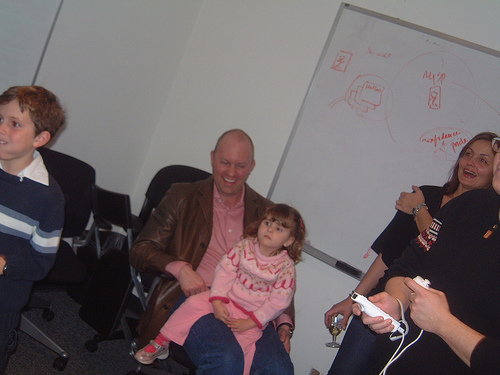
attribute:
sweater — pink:
[218, 235, 300, 330]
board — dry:
[259, 6, 499, 290]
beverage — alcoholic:
[321, 310, 346, 352]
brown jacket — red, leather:
[128, 152, 295, 358]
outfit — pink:
[160, 236, 297, 373]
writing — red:
[330, 50, 487, 162]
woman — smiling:
[370, 125, 490, 200]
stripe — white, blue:
[0, 205, 62, 260]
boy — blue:
[2, 81, 70, 358]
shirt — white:
[5, 157, 71, 308]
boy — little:
[0, 81, 75, 373]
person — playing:
[120, 82, 373, 362]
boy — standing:
[5, 73, 94, 349]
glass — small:
[323, 312, 344, 348]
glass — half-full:
[324, 314, 344, 348]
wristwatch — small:
[271, 325, 317, 337]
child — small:
[133, 200, 303, 373]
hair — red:
[255, 195, 302, 255]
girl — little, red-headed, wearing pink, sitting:
[130, 201, 307, 372]